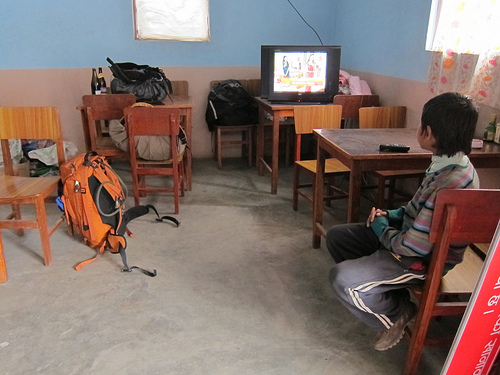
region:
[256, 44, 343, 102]
this is a television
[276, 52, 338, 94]
the television is on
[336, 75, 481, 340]
this is a boy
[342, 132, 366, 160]
this is a table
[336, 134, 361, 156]
the table is made of wood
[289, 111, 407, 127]
these are two chairs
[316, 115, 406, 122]
the chairs are wooden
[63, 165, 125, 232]
this is a rugsack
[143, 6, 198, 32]
this is a window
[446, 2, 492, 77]
these are window curtains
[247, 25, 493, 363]
Boy watching a television sitting on chair.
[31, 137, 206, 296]
backpack lying on floor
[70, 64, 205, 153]
Opened beer bottles on table.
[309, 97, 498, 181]
TV remote lying on table.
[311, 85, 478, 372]
Boy with black hair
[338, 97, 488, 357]
Boy wearing tennis shoes.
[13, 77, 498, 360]
Room with clean floor.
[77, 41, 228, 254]
Bag lying on table.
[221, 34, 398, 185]
Two women on television.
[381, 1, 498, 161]
Light coming in from blinds.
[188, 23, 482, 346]
a boy watches television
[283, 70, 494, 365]
a young boy sits at a table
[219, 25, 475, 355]
a boy sits at a table watching television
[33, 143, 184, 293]
an orange backpack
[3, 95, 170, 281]
an orange backpack is on the floor next to a chair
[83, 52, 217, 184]
a black and grey backpack is on a desk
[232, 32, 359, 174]
a television is on a table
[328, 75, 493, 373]
a boy sits in a chair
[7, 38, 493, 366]
a room full of wooden chairs and tables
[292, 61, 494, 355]
the boy wears grey and white sweatpants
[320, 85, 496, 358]
boy sitting in a chair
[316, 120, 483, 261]
wooden table in front of boy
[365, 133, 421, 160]
remote control on table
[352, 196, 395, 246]
boy's hands are clasped together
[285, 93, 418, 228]
two chairs sitting near table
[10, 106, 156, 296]
large backpack leaning against chair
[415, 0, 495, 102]
curtain in front of a window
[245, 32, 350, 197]
television on a table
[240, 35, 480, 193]
boy looking towards television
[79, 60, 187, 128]
bottles on a table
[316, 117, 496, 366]
the boy is watching the tv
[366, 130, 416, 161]
the remote is on the table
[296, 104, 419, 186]
the chairs are brown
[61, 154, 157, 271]
the backpack is orange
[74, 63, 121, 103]
there are beer bottles on the table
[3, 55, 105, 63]
the wall is blue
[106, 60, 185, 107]
there is a bag on the table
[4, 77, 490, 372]
the scene is indoors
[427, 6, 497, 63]
there is light coming through the window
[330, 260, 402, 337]
the pants have white stipes